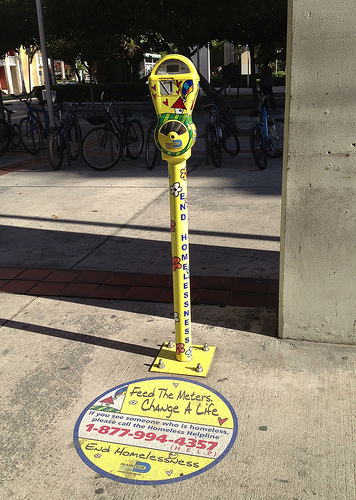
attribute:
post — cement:
[164, 162, 195, 365]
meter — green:
[145, 50, 203, 164]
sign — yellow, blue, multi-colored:
[74, 376, 237, 482]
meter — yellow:
[145, 49, 219, 380]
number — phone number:
[81, 415, 221, 460]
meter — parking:
[126, 36, 242, 170]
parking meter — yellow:
[149, 50, 221, 377]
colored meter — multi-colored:
[155, 68, 236, 201]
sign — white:
[71, 350, 258, 482]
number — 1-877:
[81, 419, 224, 461]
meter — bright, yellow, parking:
[126, 53, 293, 417]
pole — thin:
[276, 2, 345, 342]